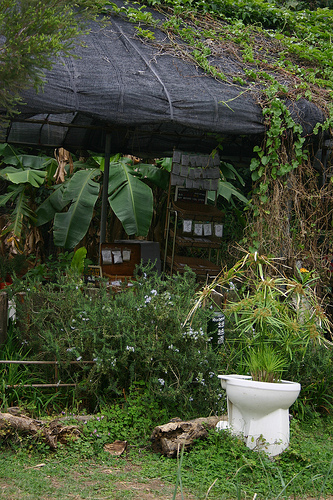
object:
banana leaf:
[107, 159, 154, 237]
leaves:
[156, 193, 165, 228]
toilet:
[215, 365, 301, 458]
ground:
[0, 415, 333, 499]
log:
[0, 408, 83, 455]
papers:
[183, 218, 192, 233]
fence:
[0, 355, 138, 393]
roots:
[248, 170, 332, 298]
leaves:
[292, 22, 315, 68]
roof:
[20, 11, 325, 137]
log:
[148, 412, 226, 458]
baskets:
[176, 212, 227, 247]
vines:
[250, 121, 281, 224]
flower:
[136, 289, 157, 311]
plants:
[0, 1, 332, 95]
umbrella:
[0, 0, 329, 280]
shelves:
[164, 188, 230, 283]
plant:
[244, 342, 288, 381]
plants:
[104, 266, 207, 411]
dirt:
[32, 460, 182, 499]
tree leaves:
[0, 150, 51, 246]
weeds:
[65, 355, 226, 434]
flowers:
[163, 292, 171, 304]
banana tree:
[51, 164, 103, 250]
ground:
[128, 461, 171, 498]